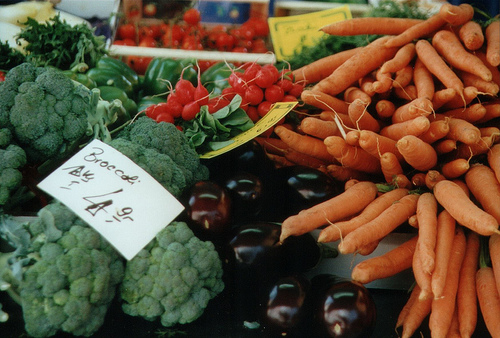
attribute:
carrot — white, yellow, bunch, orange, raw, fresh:
[431, 179, 499, 234]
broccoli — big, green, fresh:
[10, 67, 88, 152]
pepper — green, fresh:
[214, 33, 237, 54]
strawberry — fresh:
[117, 23, 138, 41]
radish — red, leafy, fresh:
[176, 61, 196, 104]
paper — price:
[36, 137, 186, 260]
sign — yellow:
[266, 6, 351, 62]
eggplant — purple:
[176, 175, 236, 246]